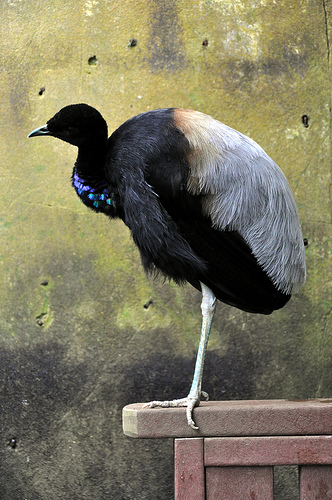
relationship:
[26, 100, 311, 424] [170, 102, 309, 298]
bird has feathers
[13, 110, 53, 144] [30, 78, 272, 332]
beak on bird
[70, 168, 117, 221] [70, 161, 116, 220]
blocks on (bird's)neck area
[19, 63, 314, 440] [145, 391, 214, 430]
bird has claws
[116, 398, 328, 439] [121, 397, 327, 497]
wooden arm of bench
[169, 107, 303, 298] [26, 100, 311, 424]
plume on bird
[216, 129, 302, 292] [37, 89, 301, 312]
plume on bird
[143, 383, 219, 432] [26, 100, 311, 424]
foot of bird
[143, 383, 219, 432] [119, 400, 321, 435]
foot on top of brick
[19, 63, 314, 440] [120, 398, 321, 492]
bird on top of stand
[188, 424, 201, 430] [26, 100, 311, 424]
claw of bird